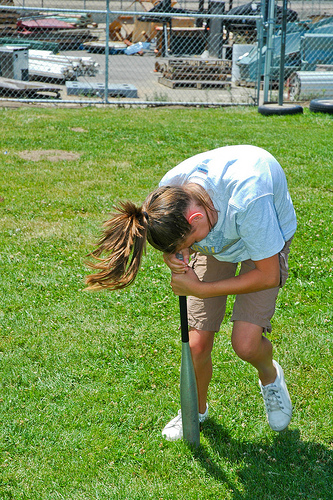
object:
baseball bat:
[179, 253, 202, 450]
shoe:
[258, 357, 293, 432]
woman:
[80, 143, 299, 445]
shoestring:
[262, 384, 285, 413]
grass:
[0, 88, 333, 499]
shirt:
[157, 143, 299, 265]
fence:
[0, 0, 333, 110]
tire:
[308, 95, 332, 116]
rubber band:
[141, 210, 150, 225]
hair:
[81, 179, 221, 295]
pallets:
[157, 76, 232, 91]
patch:
[17, 148, 35, 160]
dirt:
[24, 149, 87, 165]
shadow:
[183, 413, 333, 499]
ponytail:
[82, 198, 150, 294]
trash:
[230, 17, 333, 98]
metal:
[38, 47, 102, 79]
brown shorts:
[177, 232, 295, 338]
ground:
[0, 0, 333, 106]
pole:
[278, 0, 289, 106]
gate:
[256, 0, 269, 105]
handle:
[174, 252, 190, 344]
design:
[191, 236, 242, 258]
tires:
[257, 101, 305, 117]